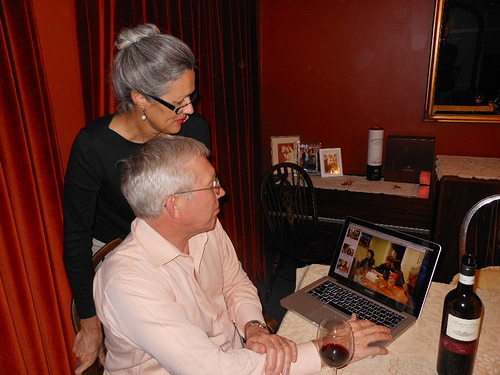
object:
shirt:
[57, 113, 218, 323]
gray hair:
[108, 19, 198, 113]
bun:
[110, 19, 158, 51]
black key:
[313, 284, 328, 294]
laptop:
[282, 219, 448, 348]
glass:
[314, 316, 356, 374]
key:
[348, 294, 354, 298]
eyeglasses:
[171, 173, 226, 192]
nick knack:
[381, 133, 441, 187]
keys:
[337, 301, 345, 306]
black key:
[366, 303, 375, 318]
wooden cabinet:
[435, 155, 499, 265]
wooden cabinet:
[274, 169, 440, 246]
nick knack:
[366, 120, 381, 177]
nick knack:
[316, 147, 345, 177]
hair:
[119, 133, 201, 219]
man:
[91, 134, 391, 373]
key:
[377, 317, 383, 322]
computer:
[276, 216, 443, 350]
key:
[349, 303, 356, 307]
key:
[311, 293, 318, 298]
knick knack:
[320, 145, 345, 179]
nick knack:
[268, 132, 302, 172]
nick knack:
[302, 142, 317, 170]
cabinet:
[262, 175, 450, 280]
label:
[442, 316, 484, 343]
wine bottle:
[419, 252, 493, 375]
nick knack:
[416, 170, 433, 198]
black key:
[337, 285, 344, 293]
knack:
[341, 179, 354, 186]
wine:
[318, 340, 350, 365]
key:
[346, 289, 353, 293]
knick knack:
[365, 127, 385, 180]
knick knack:
[337, 175, 356, 187]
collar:
[129, 214, 209, 271]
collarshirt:
[88, 214, 326, 375]